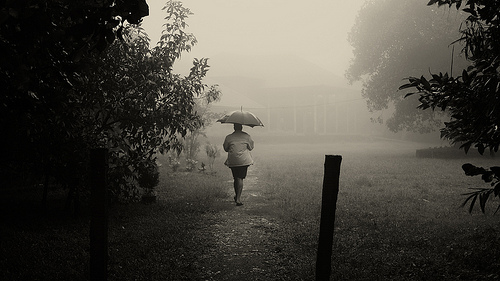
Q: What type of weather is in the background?
A: It is foggy.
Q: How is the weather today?
A: It is foggy.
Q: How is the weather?
A: It is foggy.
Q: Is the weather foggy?
A: Yes, it is foggy.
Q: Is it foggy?
A: Yes, it is foggy.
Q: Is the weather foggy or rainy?
A: It is foggy.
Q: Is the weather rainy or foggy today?
A: It is foggy.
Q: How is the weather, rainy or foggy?
A: It is foggy.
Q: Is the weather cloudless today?
A: No, it is foggy.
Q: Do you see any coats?
A: Yes, there is a coat.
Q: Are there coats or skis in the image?
A: Yes, there is a coat.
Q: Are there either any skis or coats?
A: Yes, there is a coat.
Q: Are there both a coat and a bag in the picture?
A: No, there is a coat but no bags.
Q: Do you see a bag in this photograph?
A: No, there are no bags.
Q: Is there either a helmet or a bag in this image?
A: No, there are no bags or helmets.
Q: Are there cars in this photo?
A: No, there are no cars.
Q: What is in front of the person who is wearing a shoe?
A: The building is in front of the woman.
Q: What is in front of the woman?
A: The building is in front of the woman.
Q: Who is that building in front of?
A: The building is in front of the woman.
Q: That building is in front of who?
A: The building is in front of the woman.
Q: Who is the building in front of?
A: The building is in front of the woman.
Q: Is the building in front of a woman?
A: Yes, the building is in front of a woman.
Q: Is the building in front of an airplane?
A: No, the building is in front of a woman.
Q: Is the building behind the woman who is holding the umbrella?
A: No, the building is in front of the woman.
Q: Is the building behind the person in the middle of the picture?
A: No, the building is in front of the woman.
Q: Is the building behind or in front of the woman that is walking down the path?
A: The building is in front of the woman.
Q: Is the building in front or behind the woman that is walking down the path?
A: The building is in front of the woman.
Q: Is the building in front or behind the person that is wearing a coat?
A: The building is in front of the woman.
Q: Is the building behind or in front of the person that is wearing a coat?
A: The building is in front of the woman.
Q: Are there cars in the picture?
A: No, there are no cars.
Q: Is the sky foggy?
A: Yes, the sky is foggy.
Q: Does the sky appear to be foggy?
A: Yes, the sky is foggy.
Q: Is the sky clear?
A: No, the sky is foggy.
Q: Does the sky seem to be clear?
A: No, the sky is foggy.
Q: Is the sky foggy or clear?
A: The sky is foggy.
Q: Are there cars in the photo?
A: No, there are no cars.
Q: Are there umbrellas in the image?
A: Yes, there is an umbrella.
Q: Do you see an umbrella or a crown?
A: Yes, there is an umbrella.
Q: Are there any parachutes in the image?
A: No, there are no parachutes.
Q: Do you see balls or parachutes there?
A: No, there are no parachutes or balls.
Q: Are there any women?
A: Yes, there is a woman.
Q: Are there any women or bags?
A: Yes, there is a woman.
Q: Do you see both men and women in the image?
A: No, there is a woman but no men.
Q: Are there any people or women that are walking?
A: Yes, the woman is walking.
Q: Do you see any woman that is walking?
A: Yes, there is a woman that is walking.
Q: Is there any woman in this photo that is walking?
A: Yes, there is a woman that is walking.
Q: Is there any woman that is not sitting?
A: Yes, there is a woman that is walking.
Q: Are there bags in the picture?
A: No, there are no bags.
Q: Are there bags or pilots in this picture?
A: No, there are no bags or pilots.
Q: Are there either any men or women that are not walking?
A: No, there is a woman but she is walking.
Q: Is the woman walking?
A: Yes, the woman is walking.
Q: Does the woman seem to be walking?
A: Yes, the woman is walking.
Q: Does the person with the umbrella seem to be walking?
A: Yes, the woman is walking.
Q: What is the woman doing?
A: The woman is walking.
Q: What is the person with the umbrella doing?
A: The woman is walking.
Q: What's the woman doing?
A: The woman is walking.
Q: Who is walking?
A: The woman is walking.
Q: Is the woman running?
A: No, the woman is walking.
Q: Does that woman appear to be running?
A: No, the woman is walking.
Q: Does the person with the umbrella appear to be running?
A: No, the woman is walking.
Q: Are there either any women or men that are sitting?
A: No, there is a woman but she is walking.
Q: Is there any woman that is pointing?
A: No, there is a woman but she is walking.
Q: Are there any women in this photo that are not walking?
A: No, there is a woman but she is walking.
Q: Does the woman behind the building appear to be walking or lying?
A: The woman is walking.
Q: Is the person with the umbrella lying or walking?
A: The woman is walking.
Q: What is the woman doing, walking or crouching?
A: The woman is walking.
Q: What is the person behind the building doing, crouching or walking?
A: The woman is walking.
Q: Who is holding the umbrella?
A: The woman is holding the umbrella.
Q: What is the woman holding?
A: The woman is holding the umbrella.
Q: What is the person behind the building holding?
A: The woman is holding the umbrella.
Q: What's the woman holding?
A: The woman is holding the umbrella.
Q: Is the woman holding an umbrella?
A: Yes, the woman is holding an umbrella.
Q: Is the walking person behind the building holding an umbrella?
A: Yes, the woman is holding an umbrella.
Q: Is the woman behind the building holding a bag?
A: No, the woman is holding an umbrella.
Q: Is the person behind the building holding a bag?
A: No, the woman is holding an umbrella.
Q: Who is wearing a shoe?
A: The woman is wearing a shoe.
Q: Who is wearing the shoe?
A: The woman is wearing a shoe.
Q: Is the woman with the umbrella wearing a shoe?
A: Yes, the woman is wearing a shoe.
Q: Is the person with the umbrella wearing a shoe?
A: Yes, the woman is wearing a shoe.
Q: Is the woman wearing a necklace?
A: No, the woman is wearing a shoe.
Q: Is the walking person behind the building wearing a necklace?
A: No, the woman is wearing a shoe.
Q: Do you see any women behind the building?
A: Yes, there is a woman behind the building.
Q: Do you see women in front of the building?
A: No, the woman is behind the building.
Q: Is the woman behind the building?
A: Yes, the woman is behind the building.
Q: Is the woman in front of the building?
A: No, the woman is behind the building.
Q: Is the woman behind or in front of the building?
A: The woman is behind the building.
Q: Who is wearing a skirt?
A: The woman is wearing a skirt.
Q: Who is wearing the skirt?
A: The woman is wearing a skirt.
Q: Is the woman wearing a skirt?
A: Yes, the woman is wearing a skirt.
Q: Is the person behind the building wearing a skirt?
A: Yes, the woman is wearing a skirt.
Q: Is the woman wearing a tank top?
A: No, the woman is wearing a skirt.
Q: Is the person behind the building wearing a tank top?
A: No, the woman is wearing a skirt.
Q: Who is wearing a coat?
A: The woman is wearing a coat.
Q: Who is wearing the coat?
A: The woman is wearing a coat.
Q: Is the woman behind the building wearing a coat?
A: Yes, the woman is wearing a coat.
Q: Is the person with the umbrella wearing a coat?
A: Yes, the woman is wearing a coat.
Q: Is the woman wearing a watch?
A: No, the woman is wearing a coat.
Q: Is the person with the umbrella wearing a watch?
A: No, the woman is wearing a coat.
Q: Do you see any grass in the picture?
A: Yes, there is grass.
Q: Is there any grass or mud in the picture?
A: Yes, there is grass.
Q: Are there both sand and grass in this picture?
A: No, there is grass but no sand.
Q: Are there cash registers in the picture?
A: No, there are no cash registers.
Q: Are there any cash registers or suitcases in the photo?
A: No, there are no cash registers or suitcases.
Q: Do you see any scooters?
A: No, there are no scooters.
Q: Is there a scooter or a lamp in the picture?
A: No, there are no scooters or lamps.